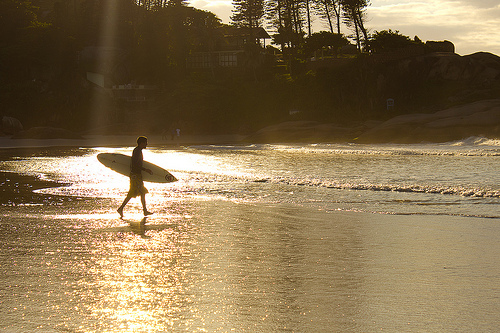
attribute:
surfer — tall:
[95, 135, 177, 221]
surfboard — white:
[98, 151, 180, 183]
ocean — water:
[203, 134, 480, 331]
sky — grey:
[371, 1, 484, 41]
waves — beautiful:
[12, 134, 499, 195]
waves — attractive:
[212, 130, 497, 200]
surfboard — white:
[92, 148, 179, 189]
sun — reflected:
[157, 143, 220, 172]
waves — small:
[248, 139, 498, 197]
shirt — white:
[173, 126, 180, 136]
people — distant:
[155, 123, 187, 143]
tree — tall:
[338, 0, 368, 51]